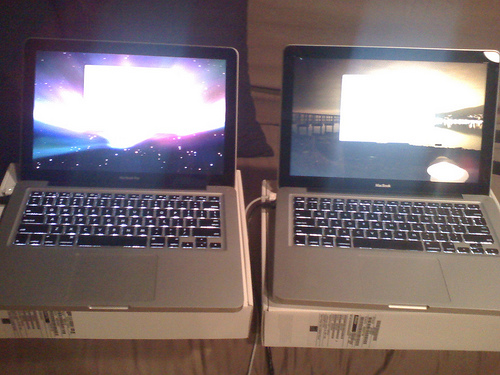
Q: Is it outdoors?
A: Yes, it is outdoors.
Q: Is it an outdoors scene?
A: Yes, it is outdoors.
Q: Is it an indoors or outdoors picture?
A: It is outdoors.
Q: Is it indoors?
A: No, it is outdoors.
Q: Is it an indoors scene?
A: No, it is outdoors.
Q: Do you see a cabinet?
A: Yes, there is a cabinet.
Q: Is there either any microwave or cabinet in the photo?
A: Yes, there is a cabinet.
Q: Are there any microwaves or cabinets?
A: Yes, there is a cabinet.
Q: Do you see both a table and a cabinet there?
A: Yes, there are both a cabinet and a table.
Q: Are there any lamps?
A: No, there are no lamps.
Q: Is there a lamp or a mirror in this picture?
A: No, there are no lamps or mirrors.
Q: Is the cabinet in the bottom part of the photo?
A: Yes, the cabinet is in the bottom of the image.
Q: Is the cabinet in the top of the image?
A: No, the cabinet is in the bottom of the image.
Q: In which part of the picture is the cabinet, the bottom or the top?
A: The cabinet is in the bottom of the image.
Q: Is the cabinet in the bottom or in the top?
A: The cabinet is in the bottom of the image.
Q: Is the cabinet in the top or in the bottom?
A: The cabinet is in the bottom of the image.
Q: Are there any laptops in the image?
A: Yes, there is a laptop.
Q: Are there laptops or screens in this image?
A: Yes, there is a laptop.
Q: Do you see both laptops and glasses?
A: No, there is a laptop but no glasses.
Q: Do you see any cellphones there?
A: No, there are no cellphones.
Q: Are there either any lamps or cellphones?
A: No, there are no cellphones or lamps.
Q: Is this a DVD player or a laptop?
A: This is a laptop.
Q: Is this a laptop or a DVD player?
A: This is a laptop.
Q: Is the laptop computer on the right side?
A: Yes, the laptop computer is on the right of the image.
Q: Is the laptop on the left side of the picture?
A: No, the laptop is on the right of the image.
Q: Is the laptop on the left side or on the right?
A: The laptop is on the right of the image.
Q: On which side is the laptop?
A: The laptop is on the right of the image.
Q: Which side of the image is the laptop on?
A: The laptop is on the right of the image.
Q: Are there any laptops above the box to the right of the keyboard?
A: Yes, there is a laptop above the box.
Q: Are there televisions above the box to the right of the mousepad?
A: No, there is a laptop above the box.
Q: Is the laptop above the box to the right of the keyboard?
A: Yes, the laptop is above the box.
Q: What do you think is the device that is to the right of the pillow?
A: The device is a laptop.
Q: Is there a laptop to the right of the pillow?
A: Yes, there is a laptop to the right of the pillow.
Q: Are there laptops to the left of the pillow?
A: No, the laptop is to the right of the pillow.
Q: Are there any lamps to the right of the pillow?
A: No, there is a laptop to the right of the pillow.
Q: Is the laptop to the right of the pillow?
A: Yes, the laptop is to the right of the pillow.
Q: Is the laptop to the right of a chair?
A: No, the laptop is to the right of the pillow.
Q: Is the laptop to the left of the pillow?
A: No, the laptop is to the right of the pillow.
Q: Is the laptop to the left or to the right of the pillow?
A: The laptop is to the right of the pillow.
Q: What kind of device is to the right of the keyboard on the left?
A: The device is a laptop.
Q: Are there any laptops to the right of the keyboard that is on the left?
A: Yes, there is a laptop to the right of the keyboard.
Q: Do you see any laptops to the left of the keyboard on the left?
A: No, the laptop is to the right of the keyboard.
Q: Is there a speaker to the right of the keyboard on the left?
A: No, there is a laptop to the right of the keyboard.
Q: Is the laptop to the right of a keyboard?
A: Yes, the laptop is to the right of a keyboard.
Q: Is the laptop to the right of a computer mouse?
A: No, the laptop is to the right of a keyboard.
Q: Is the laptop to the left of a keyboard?
A: No, the laptop is to the right of a keyboard.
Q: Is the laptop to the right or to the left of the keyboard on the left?
A: The laptop is to the right of the keyboard.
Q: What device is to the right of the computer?
A: The device is a laptop.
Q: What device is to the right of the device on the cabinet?
A: The device is a laptop.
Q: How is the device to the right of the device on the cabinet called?
A: The device is a laptop.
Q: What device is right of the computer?
A: The device is a laptop.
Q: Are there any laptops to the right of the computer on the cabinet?
A: Yes, there is a laptop to the right of the computer.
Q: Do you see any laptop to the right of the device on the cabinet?
A: Yes, there is a laptop to the right of the computer.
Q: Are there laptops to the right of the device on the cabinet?
A: Yes, there is a laptop to the right of the computer.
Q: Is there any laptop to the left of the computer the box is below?
A: No, the laptop is to the right of the computer.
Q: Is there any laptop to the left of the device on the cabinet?
A: No, the laptop is to the right of the computer.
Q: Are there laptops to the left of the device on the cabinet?
A: No, the laptop is to the right of the computer.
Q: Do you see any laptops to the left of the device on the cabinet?
A: No, the laptop is to the right of the computer.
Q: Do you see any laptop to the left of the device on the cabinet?
A: No, the laptop is to the right of the computer.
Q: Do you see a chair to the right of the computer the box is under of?
A: No, there is a laptop to the right of the computer.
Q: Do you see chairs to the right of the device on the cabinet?
A: No, there is a laptop to the right of the computer.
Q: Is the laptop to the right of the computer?
A: Yes, the laptop is to the right of the computer.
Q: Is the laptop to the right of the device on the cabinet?
A: Yes, the laptop is to the right of the computer.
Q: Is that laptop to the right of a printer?
A: No, the laptop is to the right of the computer.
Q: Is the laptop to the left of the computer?
A: No, the laptop is to the right of the computer.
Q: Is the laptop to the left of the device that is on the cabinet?
A: No, the laptop is to the right of the computer.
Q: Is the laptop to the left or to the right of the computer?
A: The laptop is to the right of the computer.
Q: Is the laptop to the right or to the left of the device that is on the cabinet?
A: The laptop is to the right of the computer.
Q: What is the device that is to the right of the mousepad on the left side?
A: The device is a laptop.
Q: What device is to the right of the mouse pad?
A: The device is a laptop.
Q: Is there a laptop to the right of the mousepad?
A: Yes, there is a laptop to the right of the mousepad.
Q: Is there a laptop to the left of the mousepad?
A: No, the laptop is to the right of the mousepad.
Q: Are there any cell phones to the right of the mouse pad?
A: No, there is a laptop to the right of the mouse pad.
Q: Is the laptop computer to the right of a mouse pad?
A: Yes, the laptop computer is to the right of a mouse pad.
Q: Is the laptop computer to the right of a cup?
A: No, the laptop computer is to the right of a mouse pad.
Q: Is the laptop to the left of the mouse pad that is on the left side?
A: No, the laptop is to the right of the mouse pad.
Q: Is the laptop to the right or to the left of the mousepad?
A: The laptop is to the right of the mousepad.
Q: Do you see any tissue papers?
A: No, there are no tissue papers.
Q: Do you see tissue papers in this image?
A: No, there are no tissue papers.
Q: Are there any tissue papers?
A: No, there are no tissue papers.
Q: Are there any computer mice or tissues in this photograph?
A: No, there are no tissues or computer mice.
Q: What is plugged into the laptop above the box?
A: The cord is plugged into the laptop.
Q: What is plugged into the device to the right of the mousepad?
A: The cord is plugged into the laptop.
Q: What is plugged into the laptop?
A: The cord is plugged into the laptop.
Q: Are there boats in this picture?
A: No, there are no boats.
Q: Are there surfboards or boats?
A: No, there are no boats or surfboards.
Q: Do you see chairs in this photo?
A: No, there are no chairs.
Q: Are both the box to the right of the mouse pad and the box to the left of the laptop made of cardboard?
A: Yes, both the box and the box are made of cardboard.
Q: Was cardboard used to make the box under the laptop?
A: Yes, the box is made of cardboard.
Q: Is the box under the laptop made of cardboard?
A: Yes, the box is made of cardboard.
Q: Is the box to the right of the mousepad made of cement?
A: No, the box is made of cardboard.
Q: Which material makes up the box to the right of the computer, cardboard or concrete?
A: The box is made of cardboard.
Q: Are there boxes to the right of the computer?
A: Yes, there is a box to the right of the computer.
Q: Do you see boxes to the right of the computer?
A: Yes, there is a box to the right of the computer.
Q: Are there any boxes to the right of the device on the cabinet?
A: Yes, there is a box to the right of the computer.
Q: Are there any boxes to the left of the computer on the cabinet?
A: No, the box is to the right of the computer.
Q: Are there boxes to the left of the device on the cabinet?
A: No, the box is to the right of the computer.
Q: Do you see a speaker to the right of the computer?
A: No, there is a box to the right of the computer.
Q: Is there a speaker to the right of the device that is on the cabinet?
A: No, there is a box to the right of the computer.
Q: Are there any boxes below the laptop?
A: Yes, there is a box below the laptop.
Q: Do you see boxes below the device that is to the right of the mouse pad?
A: Yes, there is a box below the laptop.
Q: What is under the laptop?
A: The box is under the laptop.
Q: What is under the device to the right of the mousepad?
A: The box is under the laptop.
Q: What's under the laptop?
A: The box is under the laptop.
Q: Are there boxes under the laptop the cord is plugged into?
A: Yes, there is a box under the laptop computer.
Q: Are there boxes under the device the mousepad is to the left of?
A: Yes, there is a box under the laptop computer.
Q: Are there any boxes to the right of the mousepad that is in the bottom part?
A: Yes, there is a box to the right of the mouse pad.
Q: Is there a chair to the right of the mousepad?
A: No, there is a box to the right of the mousepad.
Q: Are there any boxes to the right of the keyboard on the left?
A: Yes, there is a box to the right of the keyboard.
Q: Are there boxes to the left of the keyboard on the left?
A: No, the box is to the right of the keyboard.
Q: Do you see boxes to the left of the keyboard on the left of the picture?
A: No, the box is to the right of the keyboard.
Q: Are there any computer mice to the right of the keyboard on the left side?
A: No, there is a box to the right of the keyboard.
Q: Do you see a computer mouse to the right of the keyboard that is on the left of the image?
A: No, there is a box to the right of the keyboard.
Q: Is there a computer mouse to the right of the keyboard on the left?
A: No, there is a box to the right of the keyboard.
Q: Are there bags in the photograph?
A: No, there are no bags.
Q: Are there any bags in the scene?
A: No, there are no bags.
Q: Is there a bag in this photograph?
A: No, there are no bags.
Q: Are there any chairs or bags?
A: No, there are no bags or chairs.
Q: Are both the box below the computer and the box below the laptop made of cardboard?
A: Yes, both the box and the box are made of cardboard.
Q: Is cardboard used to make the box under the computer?
A: Yes, the box is made of cardboard.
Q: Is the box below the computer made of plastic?
A: No, the box is made of cardboard.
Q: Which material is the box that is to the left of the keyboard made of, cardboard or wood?
A: The box is made of cardboard.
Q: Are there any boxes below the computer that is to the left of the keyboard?
A: Yes, there is a box below the computer.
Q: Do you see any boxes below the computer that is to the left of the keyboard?
A: Yes, there is a box below the computer.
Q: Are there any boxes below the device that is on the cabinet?
A: Yes, there is a box below the computer.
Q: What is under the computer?
A: The box is under the computer.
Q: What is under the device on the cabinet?
A: The box is under the computer.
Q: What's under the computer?
A: The box is under the computer.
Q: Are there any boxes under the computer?
A: Yes, there is a box under the computer.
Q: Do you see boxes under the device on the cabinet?
A: Yes, there is a box under the computer.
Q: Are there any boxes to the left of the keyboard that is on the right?
A: Yes, there is a box to the left of the keyboard.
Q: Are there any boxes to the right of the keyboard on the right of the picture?
A: No, the box is to the left of the keyboard.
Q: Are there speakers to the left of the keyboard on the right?
A: No, there is a box to the left of the keyboard.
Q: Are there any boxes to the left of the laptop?
A: Yes, there is a box to the left of the laptop.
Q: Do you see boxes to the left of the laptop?
A: Yes, there is a box to the left of the laptop.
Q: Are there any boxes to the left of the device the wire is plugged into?
A: Yes, there is a box to the left of the laptop.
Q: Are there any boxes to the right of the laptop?
A: No, the box is to the left of the laptop.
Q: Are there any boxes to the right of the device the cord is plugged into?
A: No, the box is to the left of the laptop.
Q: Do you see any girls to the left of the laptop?
A: No, there is a box to the left of the laptop.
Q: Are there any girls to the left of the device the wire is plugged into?
A: No, there is a box to the left of the laptop.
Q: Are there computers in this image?
A: Yes, there is a computer.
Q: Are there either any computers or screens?
A: Yes, there is a computer.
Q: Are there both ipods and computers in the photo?
A: No, there is a computer but no ipods.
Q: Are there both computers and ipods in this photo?
A: No, there is a computer but no ipods.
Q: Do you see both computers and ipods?
A: No, there is a computer but no ipods.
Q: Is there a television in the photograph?
A: No, there are no televisions.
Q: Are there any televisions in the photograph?
A: No, there are no televisions.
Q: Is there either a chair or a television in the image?
A: No, there are no televisions or chairs.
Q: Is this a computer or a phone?
A: This is a computer.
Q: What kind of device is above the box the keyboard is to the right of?
A: The device is a computer.